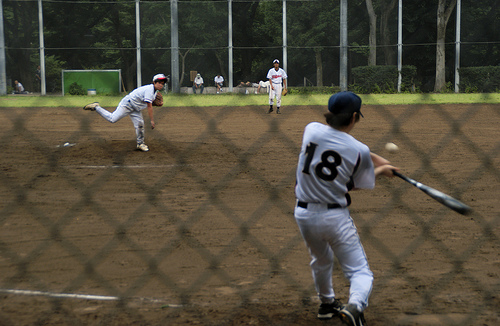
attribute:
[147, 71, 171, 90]
cap — orange, white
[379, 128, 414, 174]
baseball — white, small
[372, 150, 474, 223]
bat — long, black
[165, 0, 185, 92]
pole — long, gray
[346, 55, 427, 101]
bush — tall, green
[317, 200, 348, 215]
belt — black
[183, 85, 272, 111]
grass — green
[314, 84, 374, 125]
baseball cap — blue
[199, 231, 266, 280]
dirt patch — small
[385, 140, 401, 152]
baseball — white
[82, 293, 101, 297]
part — small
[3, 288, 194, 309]
line — white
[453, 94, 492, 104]
grass patch — green, small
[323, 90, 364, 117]
cap — blue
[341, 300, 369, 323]
shoe — black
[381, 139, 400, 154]
baseball — white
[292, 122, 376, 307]
uniform — white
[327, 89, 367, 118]
hat — blue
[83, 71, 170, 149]
baseball player — white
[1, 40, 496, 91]
fence — tall